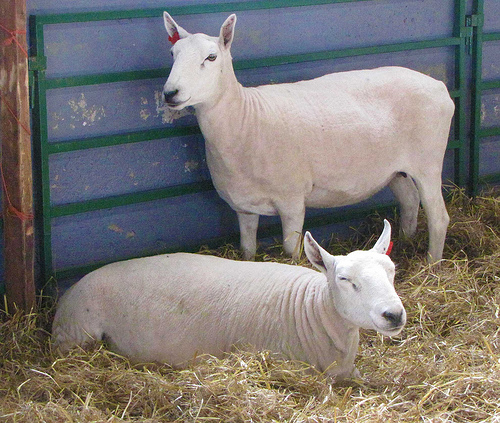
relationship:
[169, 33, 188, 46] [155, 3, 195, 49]
tag on ear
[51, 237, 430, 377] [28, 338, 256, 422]
sheep on hay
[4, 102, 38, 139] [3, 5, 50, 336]
thread tied to bar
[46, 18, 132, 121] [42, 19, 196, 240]
railings on wall